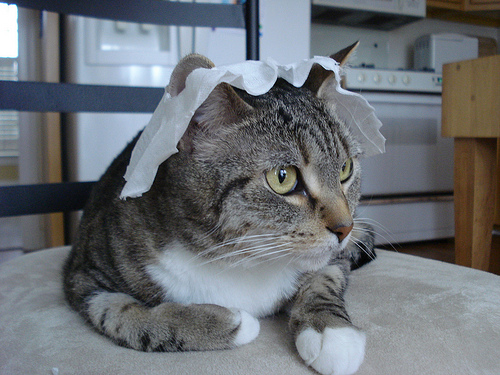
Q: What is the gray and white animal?
A: A cat.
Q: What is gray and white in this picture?
A: A cat.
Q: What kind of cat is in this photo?
A: A gray and white cat.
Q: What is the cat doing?
A: Laying down.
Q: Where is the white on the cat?
A: Chest and paws.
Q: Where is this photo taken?
A: Kitchen of a home.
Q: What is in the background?
A: Oven.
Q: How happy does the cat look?
A: Not very.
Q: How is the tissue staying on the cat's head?
A: Holes.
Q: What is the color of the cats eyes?
A: Yellow.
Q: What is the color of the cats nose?
A: Pink.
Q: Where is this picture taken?
A: A kitchen.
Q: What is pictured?
A: A gray house cat.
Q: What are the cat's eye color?
A: Green.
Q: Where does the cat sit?
A: On a chair cushion.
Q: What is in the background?
A: A white stove.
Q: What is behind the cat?
A: A white refrigerator.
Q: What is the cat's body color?
A: Gray with white markings and paws.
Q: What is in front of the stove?
A: A wooden kitchen island.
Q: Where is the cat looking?
A: Across the room.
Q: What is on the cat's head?
A: Hat.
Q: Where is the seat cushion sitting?
A: Chair frame.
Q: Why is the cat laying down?
A: Tired.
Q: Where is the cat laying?
A: On the chair.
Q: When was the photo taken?
A: Daytime.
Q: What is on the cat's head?
A: A cloth.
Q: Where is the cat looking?
A: To the right.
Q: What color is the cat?
A: Gray and white.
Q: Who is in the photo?
A: No one.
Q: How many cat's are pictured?
A: One.